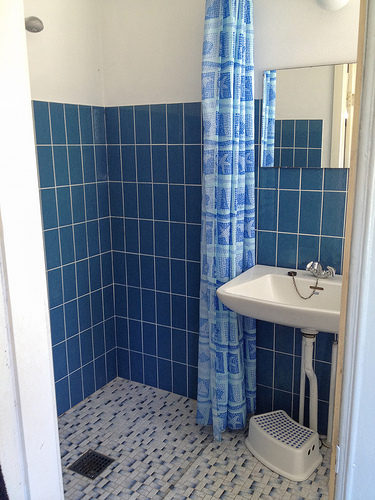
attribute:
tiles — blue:
[31, 100, 348, 437]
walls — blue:
[24, 0, 349, 438]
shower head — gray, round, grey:
[24, 15, 45, 33]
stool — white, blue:
[243, 409, 322, 484]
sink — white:
[216, 263, 343, 336]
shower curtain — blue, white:
[196, 0, 256, 443]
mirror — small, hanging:
[260, 62, 357, 170]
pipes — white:
[298, 336, 317, 439]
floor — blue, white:
[59, 374, 330, 499]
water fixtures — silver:
[304, 261, 335, 277]